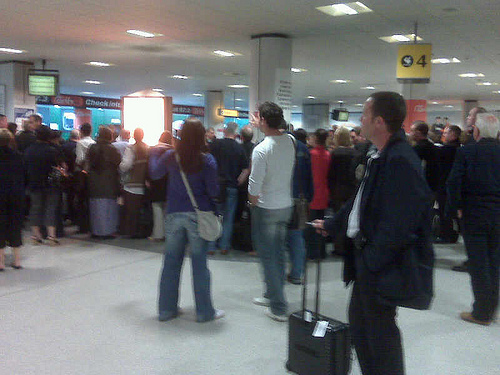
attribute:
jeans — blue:
[157, 214, 217, 324]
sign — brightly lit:
[118, 84, 175, 136]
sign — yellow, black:
[396, 40, 424, 80]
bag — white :
[168, 190, 288, 272]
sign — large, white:
[261, 62, 306, 121]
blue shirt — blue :
[145, 145, 225, 215]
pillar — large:
[247, 35, 292, 142]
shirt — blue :
[146, 146, 218, 207]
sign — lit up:
[217, 107, 240, 119]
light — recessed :
[313, 2, 381, 40]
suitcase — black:
[284, 210, 359, 374]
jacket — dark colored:
[356, 132, 435, 315]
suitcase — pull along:
[271, 224, 362, 374]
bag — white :
[172, 147, 222, 240]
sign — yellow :
[395, 42, 433, 83]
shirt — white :
[245, 135, 295, 211]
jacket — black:
[338, 127, 436, 311]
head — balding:
[468, 105, 499, 145]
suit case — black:
[285, 215, 375, 361]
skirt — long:
[86, 196, 118, 234]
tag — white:
[313, 315, 328, 340]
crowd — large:
[3, 109, 496, 371]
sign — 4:
[353, 41, 497, 121]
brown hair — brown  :
[365, 92, 405, 134]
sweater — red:
[306, 138, 334, 208]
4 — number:
[415, 53, 430, 73]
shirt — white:
[242, 132, 302, 209]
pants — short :
[2, 176, 29, 256]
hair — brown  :
[177, 116, 212, 173]